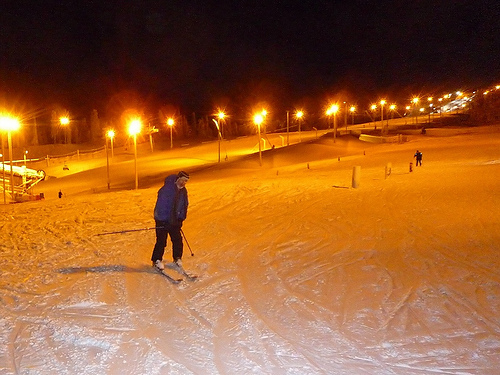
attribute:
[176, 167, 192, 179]
hat — black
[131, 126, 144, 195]
pole — long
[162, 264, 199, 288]
skis — white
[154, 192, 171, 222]
jacket — blue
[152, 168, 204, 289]
person — standing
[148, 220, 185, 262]
pants — black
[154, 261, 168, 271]
ski shoe — white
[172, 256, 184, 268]
ski shoe — white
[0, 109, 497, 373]
snow — white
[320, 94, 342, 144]
light — orange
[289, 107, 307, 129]
light — orange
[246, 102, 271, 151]
light — orange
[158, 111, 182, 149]
light — orange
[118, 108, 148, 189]
light — orange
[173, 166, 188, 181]
hat — worn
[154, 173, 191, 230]
jacket — purple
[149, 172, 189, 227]
jacket — snow jacketq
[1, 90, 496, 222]
poles — lined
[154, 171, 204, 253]
person — standing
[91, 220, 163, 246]
pole — red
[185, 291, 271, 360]
snow — white